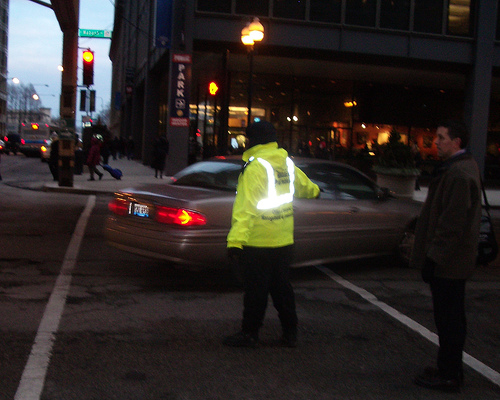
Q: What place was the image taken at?
A: It was taken at the city.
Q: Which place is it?
A: It is a city.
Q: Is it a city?
A: Yes, it is a city.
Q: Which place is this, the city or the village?
A: It is the city.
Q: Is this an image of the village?
A: No, the picture is showing the city.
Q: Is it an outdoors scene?
A: Yes, it is outdoors.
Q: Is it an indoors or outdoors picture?
A: It is outdoors.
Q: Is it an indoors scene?
A: No, it is outdoors.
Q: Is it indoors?
A: No, it is outdoors.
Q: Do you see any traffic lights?
A: Yes, there is a traffic light.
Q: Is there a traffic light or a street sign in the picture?
A: Yes, there is a traffic light.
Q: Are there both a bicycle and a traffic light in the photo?
A: No, there is a traffic light but no bicycles.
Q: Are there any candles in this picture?
A: No, there are no candles.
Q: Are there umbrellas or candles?
A: No, there are no candles or umbrellas.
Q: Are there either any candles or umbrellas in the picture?
A: No, there are no candles or umbrellas.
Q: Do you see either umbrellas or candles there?
A: No, there are no candles or umbrellas.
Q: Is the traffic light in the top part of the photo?
A: Yes, the traffic light is in the top of the image.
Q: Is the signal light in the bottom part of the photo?
A: No, the signal light is in the top of the image.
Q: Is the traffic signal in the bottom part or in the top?
A: The traffic signal is in the top of the image.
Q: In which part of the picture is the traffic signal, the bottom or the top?
A: The traffic signal is in the top of the image.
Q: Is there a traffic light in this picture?
A: Yes, there is a traffic light.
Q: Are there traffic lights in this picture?
A: Yes, there is a traffic light.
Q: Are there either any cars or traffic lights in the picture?
A: Yes, there is a traffic light.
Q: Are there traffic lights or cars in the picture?
A: Yes, there is a traffic light.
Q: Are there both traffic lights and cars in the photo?
A: Yes, there are both a traffic light and a car.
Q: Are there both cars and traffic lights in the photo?
A: Yes, there are both a traffic light and a car.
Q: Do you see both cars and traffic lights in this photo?
A: Yes, there are both a traffic light and a car.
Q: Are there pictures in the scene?
A: No, there are no pictures.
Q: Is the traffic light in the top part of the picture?
A: Yes, the traffic light is in the top of the image.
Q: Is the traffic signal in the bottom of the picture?
A: No, the traffic signal is in the top of the image.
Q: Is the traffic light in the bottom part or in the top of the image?
A: The traffic light is in the top of the image.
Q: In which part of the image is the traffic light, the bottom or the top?
A: The traffic light is in the top of the image.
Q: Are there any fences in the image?
A: No, there are no fences.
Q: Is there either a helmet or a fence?
A: No, there are no fences or helmets.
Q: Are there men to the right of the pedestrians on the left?
A: Yes, there is a man to the right of the pedestrians.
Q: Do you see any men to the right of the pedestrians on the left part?
A: Yes, there is a man to the right of the pedestrians.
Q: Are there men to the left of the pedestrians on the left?
A: No, the man is to the right of the pedestrians.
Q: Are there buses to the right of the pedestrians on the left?
A: No, there is a man to the right of the pedestrians.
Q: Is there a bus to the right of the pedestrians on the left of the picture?
A: No, there is a man to the right of the pedestrians.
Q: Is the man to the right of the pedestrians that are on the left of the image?
A: Yes, the man is to the right of the pedestrians.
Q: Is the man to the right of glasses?
A: No, the man is to the right of the pedestrians.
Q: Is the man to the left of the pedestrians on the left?
A: No, the man is to the right of the pedestrians.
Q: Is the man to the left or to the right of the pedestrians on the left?
A: The man is to the right of the pedestrians.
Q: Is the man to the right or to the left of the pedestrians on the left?
A: The man is to the right of the pedestrians.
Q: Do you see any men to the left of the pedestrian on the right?
A: Yes, there is a man to the left of the pedestrian.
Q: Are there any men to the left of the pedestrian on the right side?
A: Yes, there is a man to the left of the pedestrian.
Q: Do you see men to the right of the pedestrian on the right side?
A: No, the man is to the left of the pedestrian.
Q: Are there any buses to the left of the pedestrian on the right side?
A: No, there is a man to the left of the pedestrian.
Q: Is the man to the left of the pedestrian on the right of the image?
A: Yes, the man is to the left of the pedestrian.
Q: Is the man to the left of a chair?
A: No, the man is to the left of the pedestrian.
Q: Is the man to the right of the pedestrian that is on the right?
A: No, the man is to the left of the pedestrian.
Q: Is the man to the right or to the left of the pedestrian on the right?
A: The man is to the left of the pedestrian.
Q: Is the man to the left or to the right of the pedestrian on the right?
A: The man is to the left of the pedestrian.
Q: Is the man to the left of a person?
A: No, the man is to the right of a person.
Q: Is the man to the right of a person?
A: Yes, the man is to the right of a person.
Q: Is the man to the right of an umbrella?
A: No, the man is to the right of a person.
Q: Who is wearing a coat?
A: The man is wearing a coat.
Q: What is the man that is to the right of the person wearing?
A: The man is wearing a coat.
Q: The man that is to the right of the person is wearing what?
A: The man is wearing a coat.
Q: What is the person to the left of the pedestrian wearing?
A: The man is wearing a coat.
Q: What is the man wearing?
A: The man is wearing a coat.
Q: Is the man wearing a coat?
A: Yes, the man is wearing a coat.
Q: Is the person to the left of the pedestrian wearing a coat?
A: Yes, the man is wearing a coat.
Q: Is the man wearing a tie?
A: No, the man is wearing a coat.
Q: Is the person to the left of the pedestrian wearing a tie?
A: No, the man is wearing a coat.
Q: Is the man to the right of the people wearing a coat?
A: Yes, the man is wearing a coat.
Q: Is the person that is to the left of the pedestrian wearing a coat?
A: Yes, the man is wearing a coat.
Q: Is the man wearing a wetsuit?
A: No, the man is wearing a coat.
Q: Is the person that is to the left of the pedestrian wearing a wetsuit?
A: No, the man is wearing a coat.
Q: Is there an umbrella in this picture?
A: No, there are no umbrellas.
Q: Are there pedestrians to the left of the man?
A: Yes, there are pedestrians to the left of the man.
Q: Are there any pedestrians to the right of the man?
A: No, the pedestrians are to the left of the man.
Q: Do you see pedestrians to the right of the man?
A: No, the pedestrians are to the left of the man.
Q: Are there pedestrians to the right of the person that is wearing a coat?
A: No, the pedestrians are to the left of the man.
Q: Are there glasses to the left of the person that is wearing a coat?
A: No, there are pedestrians to the left of the man.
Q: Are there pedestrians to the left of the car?
A: Yes, there are pedestrians to the left of the car.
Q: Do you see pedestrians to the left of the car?
A: Yes, there are pedestrians to the left of the car.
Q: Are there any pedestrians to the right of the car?
A: No, the pedestrians are to the left of the car.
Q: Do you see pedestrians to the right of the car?
A: No, the pedestrians are to the left of the car.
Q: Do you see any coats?
A: Yes, there is a coat.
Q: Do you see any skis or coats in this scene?
A: Yes, there is a coat.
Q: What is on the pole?
A: The word is on the pole.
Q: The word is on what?
A: The word is on the pole.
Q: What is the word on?
A: The word is on the pole.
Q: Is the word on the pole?
A: Yes, the word is on the pole.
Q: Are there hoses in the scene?
A: No, there are no hoses.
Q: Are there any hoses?
A: No, there are no hoses.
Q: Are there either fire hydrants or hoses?
A: No, there are no hoses or fire hydrants.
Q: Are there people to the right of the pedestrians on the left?
A: Yes, there are people to the right of the pedestrians.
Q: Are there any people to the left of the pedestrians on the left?
A: No, the people are to the right of the pedestrians.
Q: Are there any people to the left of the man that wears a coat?
A: Yes, there are people to the left of the man.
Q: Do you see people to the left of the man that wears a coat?
A: Yes, there are people to the left of the man.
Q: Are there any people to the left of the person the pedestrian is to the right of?
A: Yes, there are people to the left of the man.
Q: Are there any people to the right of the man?
A: No, the people are to the left of the man.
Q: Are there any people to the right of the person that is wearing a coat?
A: No, the people are to the left of the man.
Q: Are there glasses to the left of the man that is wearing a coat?
A: No, there are people to the left of the man.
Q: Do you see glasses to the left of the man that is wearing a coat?
A: No, there are people to the left of the man.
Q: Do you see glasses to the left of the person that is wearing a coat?
A: No, there are people to the left of the man.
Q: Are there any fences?
A: No, there are no fences.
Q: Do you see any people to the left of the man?
A: Yes, there is a person to the left of the man.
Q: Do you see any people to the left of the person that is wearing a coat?
A: Yes, there is a person to the left of the man.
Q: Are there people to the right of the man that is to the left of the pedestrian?
A: No, the person is to the left of the man.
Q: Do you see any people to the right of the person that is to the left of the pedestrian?
A: No, the person is to the left of the man.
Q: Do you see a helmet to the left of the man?
A: No, there is a person to the left of the man.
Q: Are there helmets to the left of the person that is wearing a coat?
A: No, there is a person to the left of the man.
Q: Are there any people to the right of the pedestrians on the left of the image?
A: Yes, there is a person to the right of the pedestrians.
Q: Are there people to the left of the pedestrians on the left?
A: No, the person is to the right of the pedestrians.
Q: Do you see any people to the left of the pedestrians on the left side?
A: No, the person is to the right of the pedestrians.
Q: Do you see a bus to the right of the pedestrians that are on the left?
A: No, there is a person to the right of the pedestrians.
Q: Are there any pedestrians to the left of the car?
A: No, the pedestrian is to the right of the car.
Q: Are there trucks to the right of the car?
A: No, there is a pedestrian to the right of the car.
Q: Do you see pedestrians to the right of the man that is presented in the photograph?
A: Yes, there is a pedestrian to the right of the man.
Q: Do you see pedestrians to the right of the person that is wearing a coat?
A: Yes, there is a pedestrian to the right of the man.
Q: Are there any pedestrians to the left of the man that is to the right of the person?
A: No, the pedestrian is to the right of the man.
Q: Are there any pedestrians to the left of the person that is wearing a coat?
A: No, the pedestrian is to the right of the man.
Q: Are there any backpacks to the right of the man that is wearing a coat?
A: No, there is a pedestrian to the right of the man.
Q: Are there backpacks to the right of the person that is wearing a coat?
A: No, there is a pedestrian to the right of the man.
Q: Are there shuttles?
A: No, there are no shuttles.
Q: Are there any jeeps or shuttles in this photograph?
A: No, there are no shuttles or jeeps.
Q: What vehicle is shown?
A: The vehicle is a car.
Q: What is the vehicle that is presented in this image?
A: The vehicle is a car.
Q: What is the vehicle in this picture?
A: The vehicle is a car.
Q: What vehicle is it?
A: The vehicle is a car.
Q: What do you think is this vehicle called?
A: This is a car.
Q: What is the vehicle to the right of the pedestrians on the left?
A: The vehicle is a car.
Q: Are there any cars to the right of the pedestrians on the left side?
A: Yes, there is a car to the right of the pedestrians.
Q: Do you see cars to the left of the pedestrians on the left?
A: No, the car is to the right of the pedestrians.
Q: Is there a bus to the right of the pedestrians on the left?
A: No, there is a car to the right of the pedestrians.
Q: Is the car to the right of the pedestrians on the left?
A: Yes, the car is to the right of the pedestrians.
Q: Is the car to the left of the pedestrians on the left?
A: No, the car is to the right of the pedestrians.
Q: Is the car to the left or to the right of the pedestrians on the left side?
A: The car is to the right of the pedestrians.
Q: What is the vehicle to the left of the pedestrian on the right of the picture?
A: The vehicle is a car.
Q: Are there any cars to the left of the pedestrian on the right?
A: Yes, there is a car to the left of the pedestrian.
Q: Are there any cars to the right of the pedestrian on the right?
A: No, the car is to the left of the pedestrian.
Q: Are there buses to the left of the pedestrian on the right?
A: No, there is a car to the left of the pedestrian.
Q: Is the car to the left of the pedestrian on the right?
A: Yes, the car is to the left of the pedestrian.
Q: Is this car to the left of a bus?
A: No, the car is to the left of the pedestrian.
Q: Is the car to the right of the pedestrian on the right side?
A: No, the car is to the left of the pedestrian.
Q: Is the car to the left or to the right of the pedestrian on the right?
A: The car is to the left of the pedestrian.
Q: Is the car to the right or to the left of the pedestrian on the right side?
A: The car is to the left of the pedestrian.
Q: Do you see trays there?
A: No, there are no trays.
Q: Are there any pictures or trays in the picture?
A: No, there are no trays or pictures.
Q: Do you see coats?
A: Yes, there is a coat.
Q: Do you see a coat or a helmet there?
A: Yes, there is a coat.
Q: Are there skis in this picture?
A: No, there are no skis.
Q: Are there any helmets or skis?
A: No, there are no skis or helmets.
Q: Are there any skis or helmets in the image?
A: No, there are no skis or helmets.